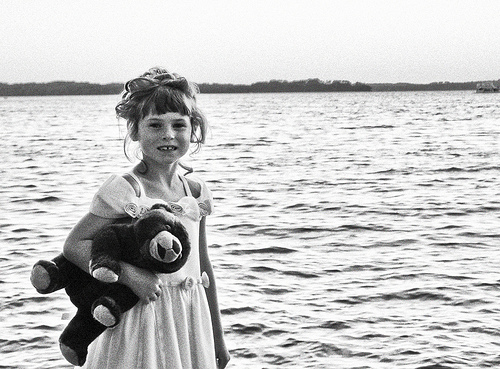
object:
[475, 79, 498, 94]
dock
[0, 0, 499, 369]
picture taken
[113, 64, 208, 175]
style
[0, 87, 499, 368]
water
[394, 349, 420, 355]
ripple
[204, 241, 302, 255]
ripple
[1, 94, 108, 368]
ripples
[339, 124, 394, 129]
ripple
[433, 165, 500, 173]
ripple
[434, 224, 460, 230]
ripple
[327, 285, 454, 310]
ripple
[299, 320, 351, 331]
ripple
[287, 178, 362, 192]
ripple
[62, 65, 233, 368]
girl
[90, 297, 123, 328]
paw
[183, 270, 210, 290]
bows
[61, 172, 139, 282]
arm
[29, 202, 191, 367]
bear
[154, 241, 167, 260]
mouth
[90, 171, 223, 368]
dress